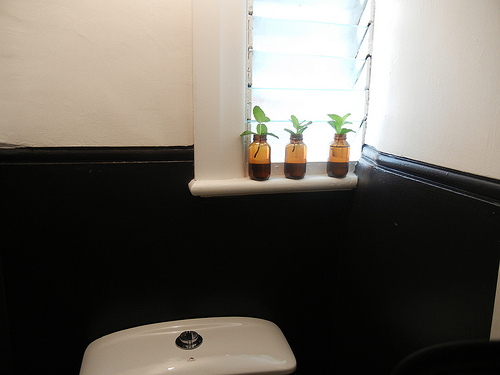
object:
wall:
[457, 1, 500, 36]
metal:
[174, 330, 204, 350]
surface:
[78, 316, 299, 375]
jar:
[248, 134, 272, 181]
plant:
[239, 105, 279, 139]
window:
[243, 0, 370, 178]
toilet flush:
[174, 330, 203, 350]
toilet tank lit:
[80, 316, 297, 375]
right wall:
[369, 71, 402, 120]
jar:
[284, 135, 307, 179]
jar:
[326, 133, 350, 178]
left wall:
[1, 146, 195, 307]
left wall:
[0, 0, 195, 143]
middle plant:
[283, 114, 313, 135]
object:
[489, 267, 500, 341]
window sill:
[188, 170, 359, 197]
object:
[369, 329, 499, 375]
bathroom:
[0, 0, 500, 375]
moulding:
[0, 143, 193, 164]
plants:
[327, 113, 357, 135]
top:
[78, 316, 297, 375]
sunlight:
[248, 0, 378, 152]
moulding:
[193, 0, 246, 180]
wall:
[449, 162, 499, 186]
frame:
[194, 0, 245, 179]